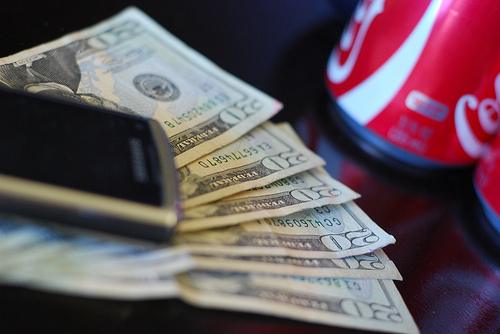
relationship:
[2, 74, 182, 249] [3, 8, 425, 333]
cell phone on money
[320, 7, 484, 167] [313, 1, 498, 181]
can of coca cola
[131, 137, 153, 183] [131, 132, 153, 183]
cellphone brand of cellphone brand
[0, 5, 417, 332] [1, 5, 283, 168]
stack of bill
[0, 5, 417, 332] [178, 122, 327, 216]
stack of bill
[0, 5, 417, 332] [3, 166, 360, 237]
stack of bill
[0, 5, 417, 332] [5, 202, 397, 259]
stack of bill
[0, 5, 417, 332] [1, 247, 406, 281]
stack of bill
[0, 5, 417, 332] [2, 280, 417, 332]
stack of bill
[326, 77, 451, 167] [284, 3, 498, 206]
bottom of can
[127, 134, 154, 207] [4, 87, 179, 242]
phone logo on cell phone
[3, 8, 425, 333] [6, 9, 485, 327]
money on table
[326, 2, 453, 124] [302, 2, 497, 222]
white stripe on soda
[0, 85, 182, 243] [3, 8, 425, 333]
cell phone on top of money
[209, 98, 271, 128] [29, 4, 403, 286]
number twenty on bill